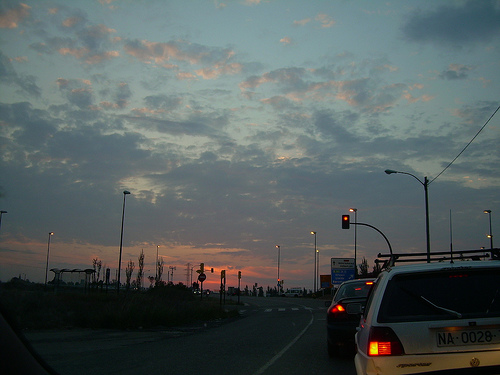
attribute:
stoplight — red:
[188, 259, 215, 289]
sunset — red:
[163, 233, 261, 311]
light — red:
[338, 213, 352, 225]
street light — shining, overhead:
[40, 227, 56, 285]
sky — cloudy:
[145, 64, 456, 206]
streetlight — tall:
[115, 189, 133, 284]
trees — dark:
[91, 251, 181, 305]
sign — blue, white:
[325, 253, 361, 292]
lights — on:
[322, 260, 432, 374]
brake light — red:
[367, 339, 391, 357]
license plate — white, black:
[432, 332, 498, 353]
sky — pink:
[138, 231, 285, 287]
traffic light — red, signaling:
[337, 215, 362, 225]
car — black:
[304, 259, 392, 357]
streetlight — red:
[340, 215, 349, 230]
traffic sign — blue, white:
[329, 255, 357, 285]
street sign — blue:
[331, 257, 358, 289]